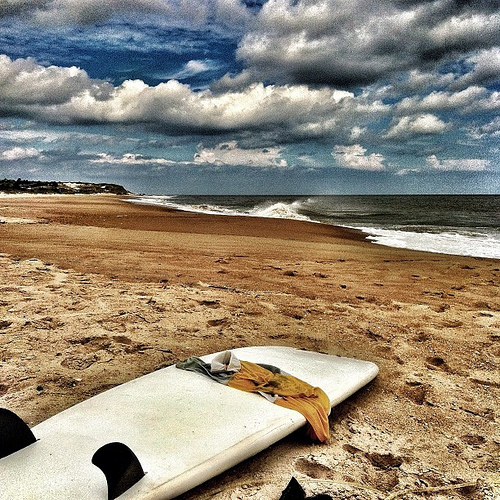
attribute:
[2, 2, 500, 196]
sky — pretty, blue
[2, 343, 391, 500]
surfboard — white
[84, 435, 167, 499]
fin — black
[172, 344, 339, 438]
clothes — left behind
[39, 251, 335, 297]
sand — smoothed, brown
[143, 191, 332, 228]
waves — breaking, stronger, crashing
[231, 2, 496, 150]
clouds — storm clouds, rolling, gray, white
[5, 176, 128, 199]
outcropping — rocky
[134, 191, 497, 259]
ocean — water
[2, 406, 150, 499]
fins — black